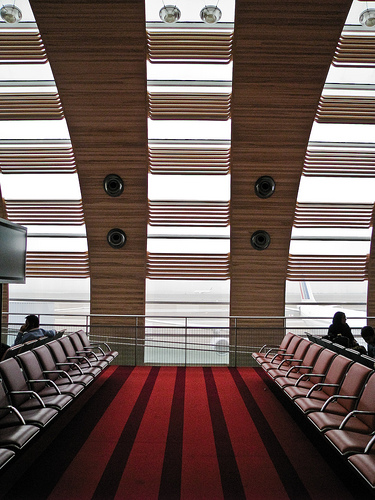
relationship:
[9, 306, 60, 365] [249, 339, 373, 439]
man on seat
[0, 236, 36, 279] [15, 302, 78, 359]
tv over man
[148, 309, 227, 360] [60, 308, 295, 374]
ramp behind fence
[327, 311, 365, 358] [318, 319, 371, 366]
woman on chair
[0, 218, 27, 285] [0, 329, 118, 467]
tv above seats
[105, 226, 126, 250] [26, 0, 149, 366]
object on wood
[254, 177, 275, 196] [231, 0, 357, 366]
object on wood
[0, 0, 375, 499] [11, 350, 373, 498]
carpet on floor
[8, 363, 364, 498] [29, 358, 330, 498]
carpet with stripes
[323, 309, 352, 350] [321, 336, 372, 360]
woman sitting on a chair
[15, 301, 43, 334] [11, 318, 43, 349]
head of a person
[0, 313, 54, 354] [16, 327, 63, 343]
man in shirt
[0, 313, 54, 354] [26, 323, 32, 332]
man talking on cellphone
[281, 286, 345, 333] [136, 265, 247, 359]
plane outside window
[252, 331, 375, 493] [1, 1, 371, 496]
chair at airport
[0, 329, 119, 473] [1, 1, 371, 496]
chair at airport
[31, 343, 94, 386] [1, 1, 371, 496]
chair at airport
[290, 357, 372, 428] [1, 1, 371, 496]
chair at airport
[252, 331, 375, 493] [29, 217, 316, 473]
chair at airport